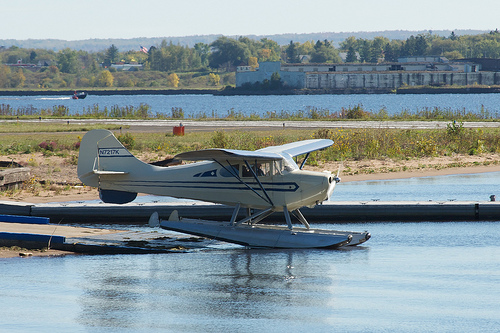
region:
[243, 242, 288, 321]
part of a water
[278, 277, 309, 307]
part of a shade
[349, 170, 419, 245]
part of a bridge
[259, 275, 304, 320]
part of a shade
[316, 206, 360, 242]
part of a plane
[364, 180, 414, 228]
part of a bridge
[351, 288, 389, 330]
part of a water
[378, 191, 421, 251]
part of a brif=dge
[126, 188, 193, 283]
part of a plane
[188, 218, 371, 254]
rudder under the plate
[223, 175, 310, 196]
blue line on side of the plane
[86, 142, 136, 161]
words on side of the plane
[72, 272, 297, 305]
blue water in the bay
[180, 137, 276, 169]
wide wing on the plane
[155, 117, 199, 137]
large red barrel on ground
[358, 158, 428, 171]
dirt on side of water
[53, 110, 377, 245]
small water plane in water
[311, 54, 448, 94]
white houses with yellow roofs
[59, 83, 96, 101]
blue boat racing in the water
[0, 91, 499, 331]
The water is blue.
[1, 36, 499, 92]
Trees are in the background.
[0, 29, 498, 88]
The trees have leaves.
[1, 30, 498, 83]
The leaves are green.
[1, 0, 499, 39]
The sky is blue.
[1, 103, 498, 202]
The grass is green.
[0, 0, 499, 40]
The sky is clear.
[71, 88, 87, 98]
A boat is in the water.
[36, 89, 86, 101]
The boat is making waves.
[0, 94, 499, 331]
The water is calm.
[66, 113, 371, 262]
A sea-faring plane.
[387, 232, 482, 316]
Cool, rippling water.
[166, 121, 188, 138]
A red block protruding from the ground.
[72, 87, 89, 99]
A boat in the background.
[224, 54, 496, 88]
A large building in the distance.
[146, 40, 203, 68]
A large growth of trees.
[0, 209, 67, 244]
Blue curb stumps, parallel to each other.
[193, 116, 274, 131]
A small section of road.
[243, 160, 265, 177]
A man in the cockpit of a plane.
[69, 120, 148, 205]
The tail of a plane.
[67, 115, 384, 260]
white plane flying low over water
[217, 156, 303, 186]
cockpit of white airplane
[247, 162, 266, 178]
person piloting white airplane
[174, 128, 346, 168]
two wings of white airplane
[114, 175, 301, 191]
black stripes on white plane's side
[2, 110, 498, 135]
path in between two stretches of grass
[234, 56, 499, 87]
houses along shoreline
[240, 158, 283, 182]
person piloting white airplane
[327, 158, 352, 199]
propellor on front of white airplane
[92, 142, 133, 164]
black lettering on white airplane